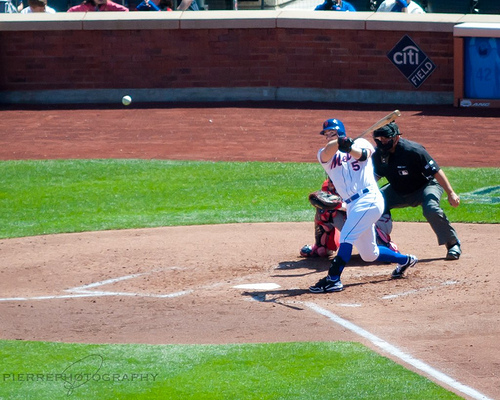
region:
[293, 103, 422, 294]
player following through on his swing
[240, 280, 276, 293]
white home plate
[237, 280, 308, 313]
shadow of the batter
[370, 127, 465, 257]
umpire crouched behind the catcher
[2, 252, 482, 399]
white chalk lines on the field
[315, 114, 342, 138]
blue helmet of the batter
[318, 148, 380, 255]
white uniform of the batter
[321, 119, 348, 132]
the helmet is blue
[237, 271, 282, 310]
home plate is white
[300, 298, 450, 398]
the line is white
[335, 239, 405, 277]
the socks are blue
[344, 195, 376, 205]
the belt is blue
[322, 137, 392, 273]
the uniform is white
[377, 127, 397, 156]
the face mask is blue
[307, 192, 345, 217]
the mit is black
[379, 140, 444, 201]
the shirt is black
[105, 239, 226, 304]
A dirt track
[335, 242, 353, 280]
Blue socks on the legs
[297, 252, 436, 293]
Sport shoes on the legs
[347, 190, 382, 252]
White pants in the photo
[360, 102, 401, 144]
A baseball bat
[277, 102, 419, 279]
A player swinging a baseball bat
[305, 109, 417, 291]
a baseball player at bat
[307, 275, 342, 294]
a black and white athletic shoe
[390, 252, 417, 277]
a black and white athletic shoe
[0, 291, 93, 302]
a white marked foul line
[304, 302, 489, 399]
a white marked foul line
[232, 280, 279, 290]
a baseball home plate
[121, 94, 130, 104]
a baseball in flight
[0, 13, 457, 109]
a short brick wall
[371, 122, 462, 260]
a baseball umpire crouching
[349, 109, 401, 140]
a brown baseball bat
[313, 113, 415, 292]
baseball player who has just hit the ball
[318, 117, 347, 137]
blue helmet the batter is wearing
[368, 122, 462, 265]
umpire standing behind the catcher and batter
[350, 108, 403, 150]
bat the batter is holding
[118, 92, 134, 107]
white baseball the player has hit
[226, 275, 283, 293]
white pentagon that indicates home plate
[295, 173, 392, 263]
catcher who is squatting behind the batter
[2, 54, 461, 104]
brick wall behind the field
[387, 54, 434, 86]
citi field sign haning on the wall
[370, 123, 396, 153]
mask the umpire is wearing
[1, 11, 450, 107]
brick and cpncrete wall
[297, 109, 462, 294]
catcher, ump, and hitter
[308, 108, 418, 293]
player hitting baseball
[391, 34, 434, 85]
navy blue and white sign on the wall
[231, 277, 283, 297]
home base plate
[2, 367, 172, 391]
name of the photography company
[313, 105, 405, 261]
a man playing baseball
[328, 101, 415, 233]
a man swinging a bat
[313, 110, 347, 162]
a man wearing a helmet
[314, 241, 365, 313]
a man wearing cliets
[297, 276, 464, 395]
a white line on the field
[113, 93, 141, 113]
a baseball in the air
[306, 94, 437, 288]
a man hitting a ball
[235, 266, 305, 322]
a white baseball plate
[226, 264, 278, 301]
a white home plate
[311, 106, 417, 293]
A batter for the Mets.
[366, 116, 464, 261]
The umpire, dressed in black.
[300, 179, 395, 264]
The catcher for the other team.